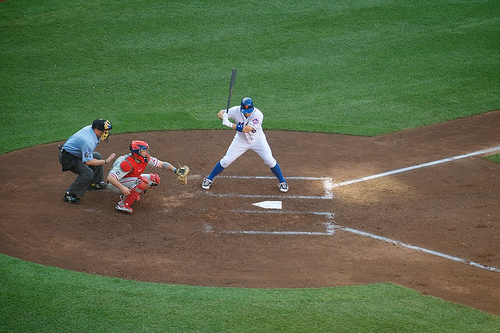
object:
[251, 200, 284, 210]
home base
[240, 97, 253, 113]
helmet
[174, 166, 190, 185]
glove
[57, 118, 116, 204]
referee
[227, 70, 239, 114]
bat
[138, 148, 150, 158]
mask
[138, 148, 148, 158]
face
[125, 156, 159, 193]
gear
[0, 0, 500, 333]
field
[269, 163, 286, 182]
sock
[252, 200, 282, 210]
plate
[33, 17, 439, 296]
game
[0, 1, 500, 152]
grass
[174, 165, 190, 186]
mitt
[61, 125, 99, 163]
shirt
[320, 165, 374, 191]
sun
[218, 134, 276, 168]
pants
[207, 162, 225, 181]
socks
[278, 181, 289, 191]
shoe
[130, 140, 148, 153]
helmet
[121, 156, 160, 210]
guard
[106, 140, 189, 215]
catcher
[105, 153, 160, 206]
uniform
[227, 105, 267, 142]
jersey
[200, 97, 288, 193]
people